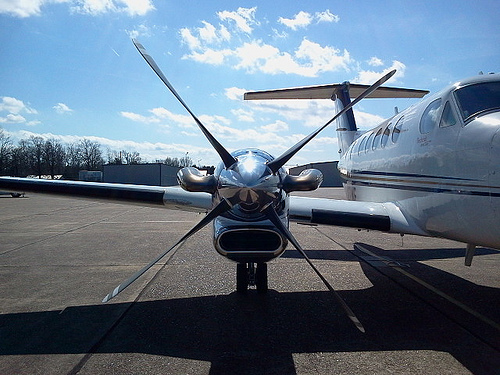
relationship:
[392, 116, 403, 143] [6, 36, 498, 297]
window on airplane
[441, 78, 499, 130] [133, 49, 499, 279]
windshield on plane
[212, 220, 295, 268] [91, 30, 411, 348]
engine on plane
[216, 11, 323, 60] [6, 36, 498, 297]
clouds above airplane